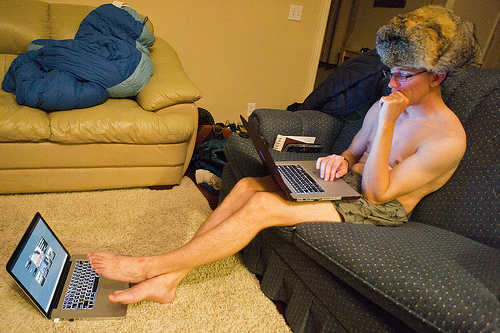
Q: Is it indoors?
A: Yes, it is indoors.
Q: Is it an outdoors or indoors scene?
A: It is indoors.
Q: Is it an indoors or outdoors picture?
A: It is indoors.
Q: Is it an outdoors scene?
A: No, it is indoors.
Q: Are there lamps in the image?
A: No, there are no lamps.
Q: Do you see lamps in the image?
A: No, there are no lamps.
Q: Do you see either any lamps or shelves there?
A: No, there are no lamps or shelves.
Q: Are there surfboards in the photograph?
A: No, there are no surfboards.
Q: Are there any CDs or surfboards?
A: No, there are no surfboards or cds.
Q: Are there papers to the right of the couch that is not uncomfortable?
A: Yes, there are papers to the right of the couch.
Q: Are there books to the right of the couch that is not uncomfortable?
A: No, there are papers to the right of the couch.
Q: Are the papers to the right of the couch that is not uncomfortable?
A: Yes, the papers are to the right of the couch.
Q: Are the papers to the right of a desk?
A: No, the papers are to the right of the couch.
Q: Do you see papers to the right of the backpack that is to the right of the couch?
A: Yes, there are papers to the right of the backpack.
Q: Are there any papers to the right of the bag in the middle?
A: Yes, there are papers to the right of the backpack.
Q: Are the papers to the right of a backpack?
A: Yes, the papers are to the right of a backpack.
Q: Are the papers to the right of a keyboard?
A: No, the papers are to the right of a backpack.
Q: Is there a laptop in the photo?
A: Yes, there is a laptop.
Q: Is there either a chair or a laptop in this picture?
A: Yes, there is a laptop.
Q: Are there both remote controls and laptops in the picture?
A: No, there is a laptop but no remote controls.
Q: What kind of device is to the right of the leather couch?
A: The device is a laptop.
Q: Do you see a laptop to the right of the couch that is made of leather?
A: Yes, there is a laptop to the right of the couch.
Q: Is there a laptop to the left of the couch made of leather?
A: No, the laptop is to the right of the couch.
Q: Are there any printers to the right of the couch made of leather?
A: No, there is a laptop to the right of the couch.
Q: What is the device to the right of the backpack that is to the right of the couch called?
A: The device is a laptop.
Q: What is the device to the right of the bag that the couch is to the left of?
A: The device is a laptop.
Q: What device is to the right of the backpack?
A: The device is a laptop.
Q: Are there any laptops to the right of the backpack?
A: Yes, there is a laptop to the right of the backpack.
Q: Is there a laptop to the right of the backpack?
A: Yes, there is a laptop to the right of the backpack.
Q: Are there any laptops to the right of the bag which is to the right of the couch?
A: Yes, there is a laptop to the right of the backpack.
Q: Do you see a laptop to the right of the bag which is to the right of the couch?
A: Yes, there is a laptop to the right of the backpack.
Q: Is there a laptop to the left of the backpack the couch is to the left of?
A: No, the laptop is to the right of the backpack.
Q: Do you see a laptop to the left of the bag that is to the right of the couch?
A: No, the laptop is to the right of the backpack.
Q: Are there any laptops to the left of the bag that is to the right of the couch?
A: No, the laptop is to the right of the backpack.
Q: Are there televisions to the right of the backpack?
A: No, there is a laptop to the right of the backpack.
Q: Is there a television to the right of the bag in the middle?
A: No, there is a laptop to the right of the backpack.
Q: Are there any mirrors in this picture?
A: No, there are no mirrors.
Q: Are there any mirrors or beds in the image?
A: No, there are no mirrors or beds.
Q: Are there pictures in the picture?
A: No, there are no pictures.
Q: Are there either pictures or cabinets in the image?
A: No, there are no pictures or cabinets.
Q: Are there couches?
A: Yes, there is a couch.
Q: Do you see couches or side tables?
A: Yes, there is a couch.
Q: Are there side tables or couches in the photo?
A: Yes, there is a couch.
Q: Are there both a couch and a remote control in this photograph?
A: No, there is a couch but no remote controls.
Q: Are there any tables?
A: No, there are no tables.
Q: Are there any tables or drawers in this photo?
A: No, there are no tables or drawers.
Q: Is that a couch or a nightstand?
A: That is a couch.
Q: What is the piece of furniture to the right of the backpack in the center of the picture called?
A: The piece of furniture is a couch.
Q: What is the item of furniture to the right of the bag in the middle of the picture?
A: The piece of furniture is a couch.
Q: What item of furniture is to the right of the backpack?
A: The piece of furniture is a couch.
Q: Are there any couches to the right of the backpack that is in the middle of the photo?
A: Yes, there is a couch to the right of the backpack.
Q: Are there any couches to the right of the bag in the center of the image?
A: Yes, there is a couch to the right of the backpack.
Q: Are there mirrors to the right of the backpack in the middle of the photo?
A: No, there is a couch to the right of the backpack.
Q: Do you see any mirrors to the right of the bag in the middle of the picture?
A: No, there is a couch to the right of the backpack.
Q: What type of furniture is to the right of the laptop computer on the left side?
A: The piece of furniture is a couch.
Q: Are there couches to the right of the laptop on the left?
A: Yes, there is a couch to the right of the laptop.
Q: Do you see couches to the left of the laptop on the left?
A: No, the couch is to the right of the laptop.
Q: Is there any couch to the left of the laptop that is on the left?
A: No, the couch is to the right of the laptop.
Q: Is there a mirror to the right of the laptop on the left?
A: No, there is a couch to the right of the laptop.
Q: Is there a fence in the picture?
A: No, there are no fences.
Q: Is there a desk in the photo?
A: No, there are no desks.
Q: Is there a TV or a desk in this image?
A: No, there are no desks or televisions.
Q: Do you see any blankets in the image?
A: Yes, there is a blanket.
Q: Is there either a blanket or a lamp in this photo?
A: Yes, there is a blanket.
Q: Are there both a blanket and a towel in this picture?
A: No, there is a blanket but no towels.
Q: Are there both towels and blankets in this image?
A: No, there is a blanket but no towels.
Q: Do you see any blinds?
A: No, there are no blinds.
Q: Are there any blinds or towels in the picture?
A: No, there are no blinds or towels.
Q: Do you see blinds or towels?
A: No, there are no blinds or towels.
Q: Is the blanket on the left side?
A: Yes, the blanket is on the left of the image.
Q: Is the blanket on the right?
A: No, the blanket is on the left of the image.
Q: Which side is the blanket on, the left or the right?
A: The blanket is on the left of the image.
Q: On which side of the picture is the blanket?
A: The blanket is on the left of the image.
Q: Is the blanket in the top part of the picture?
A: Yes, the blanket is in the top of the image.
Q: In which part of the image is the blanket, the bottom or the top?
A: The blanket is in the top of the image.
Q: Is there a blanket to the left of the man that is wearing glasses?
A: Yes, there is a blanket to the left of the man.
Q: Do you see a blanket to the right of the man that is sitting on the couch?
A: No, the blanket is to the left of the man.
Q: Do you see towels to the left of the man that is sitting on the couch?
A: No, there is a blanket to the left of the man.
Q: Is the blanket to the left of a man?
A: Yes, the blanket is to the left of a man.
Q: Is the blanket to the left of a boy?
A: No, the blanket is to the left of a man.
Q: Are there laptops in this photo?
A: Yes, there is a laptop.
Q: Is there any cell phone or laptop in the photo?
A: Yes, there is a laptop.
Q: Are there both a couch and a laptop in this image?
A: Yes, there are both a laptop and a couch.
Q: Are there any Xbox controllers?
A: No, there are no Xbox controllers.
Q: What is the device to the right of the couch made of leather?
A: The device is a laptop.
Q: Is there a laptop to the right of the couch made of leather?
A: Yes, there is a laptop to the right of the couch.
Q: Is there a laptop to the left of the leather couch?
A: No, the laptop is to the right of the couch.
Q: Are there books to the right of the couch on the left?
A: No, there is a laptop to the right of the couch.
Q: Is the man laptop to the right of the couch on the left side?
A: Yes, the laptop is to the right of the couch.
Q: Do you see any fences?
A: No, there are no fences.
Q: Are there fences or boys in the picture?
A: No, there are no fences or boys.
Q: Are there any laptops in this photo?
A: Yes, there is a laptop.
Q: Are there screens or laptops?
A: Yes, there is a laptop.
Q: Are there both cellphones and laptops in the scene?
A: No, there is a laptop but no cell phones.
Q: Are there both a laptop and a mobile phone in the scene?
A: No, there is a laptop but no cell phones.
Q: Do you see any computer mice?
A: No, there are no computer mice.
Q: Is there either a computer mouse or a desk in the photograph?
A: No, there are no computer mice or desks.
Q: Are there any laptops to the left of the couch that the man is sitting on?
A: Yes, there is a laptop to the left of the couch.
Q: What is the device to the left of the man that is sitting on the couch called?
A: The device is a laptop.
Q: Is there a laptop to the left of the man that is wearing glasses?
A: Yes, there is a laptop to the left of the man.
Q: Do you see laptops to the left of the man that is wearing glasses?
A: Yes, there is a laptop to the left of the man.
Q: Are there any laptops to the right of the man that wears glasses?
A: No, the laptop is to the left of the man.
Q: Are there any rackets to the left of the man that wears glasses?
A: No, there is a laptop to the left of the man.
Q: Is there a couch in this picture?
A: Yes, there is a couch.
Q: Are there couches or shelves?
A: Yes, there is a couch.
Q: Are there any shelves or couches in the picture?
A: Yes, there is a couch.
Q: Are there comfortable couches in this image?
A: Yes, there is a comfortable couch.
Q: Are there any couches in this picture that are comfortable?
A: Yes, there is a couch that is comfortable.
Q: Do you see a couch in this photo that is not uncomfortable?
A: Yes, there is an comfortable couch.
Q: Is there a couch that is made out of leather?
A: Yes, there is a couch that is made of leather.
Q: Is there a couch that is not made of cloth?
A: Yes, there is a couch that is made of leather.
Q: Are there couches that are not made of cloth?
A: Yes, there is a couch that is made of leather.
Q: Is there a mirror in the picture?
A: No, there are no mirrors.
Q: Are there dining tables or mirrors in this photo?
A: No, there are no mirrors or dining tables.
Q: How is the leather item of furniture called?
A: The piece of furniture is a couch.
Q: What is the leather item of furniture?
A: The piece of furniture is a couch.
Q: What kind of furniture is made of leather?
A: The furniture is a couch.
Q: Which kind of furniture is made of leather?
A: The furniture is a couch.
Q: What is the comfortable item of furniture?
A: The piece of furniture is a couch.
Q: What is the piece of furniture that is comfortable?
A: The piece of furniture is a couch.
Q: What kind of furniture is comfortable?
A: The furniture is a couch.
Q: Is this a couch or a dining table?
A: This is a couch.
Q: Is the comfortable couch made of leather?
A: Yes, the couch is made of leather.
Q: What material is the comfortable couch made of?
A: The couch is made of leather.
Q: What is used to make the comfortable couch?
A: The couch is made of leather.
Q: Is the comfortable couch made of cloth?
A: No, the couch is made of leather.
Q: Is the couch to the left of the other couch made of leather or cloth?
A: The couch is made of leather.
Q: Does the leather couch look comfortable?
A: Yes, the couch is comfortable.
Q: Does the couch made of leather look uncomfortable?
A: No, the couch is comfortable.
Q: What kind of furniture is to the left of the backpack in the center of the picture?
A: The piece of furniture is a couch.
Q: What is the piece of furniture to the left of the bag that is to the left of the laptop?
A: The piece of furniture is a couch.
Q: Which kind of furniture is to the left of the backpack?
A: The piece of furniture is a couch.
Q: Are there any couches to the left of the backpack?
A: Yes, there is a couch to the left of the backpack.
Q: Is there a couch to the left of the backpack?
A: Yes, there is a couch to the left of the backpack.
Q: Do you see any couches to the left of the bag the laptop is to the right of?
A: Yes, there is a couch to the left of the backpack.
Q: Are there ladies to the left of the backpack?
A: No, there is a couch to the left of the backpack.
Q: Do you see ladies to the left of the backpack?
A: No, there is a couch to the left of the backpack.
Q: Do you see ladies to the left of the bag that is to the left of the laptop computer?
A: No, there is a couch to the left of the backpack.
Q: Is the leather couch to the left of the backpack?
A: Yes, the couch is to the left of the backpack.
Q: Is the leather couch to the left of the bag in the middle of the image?
A: Yes, the couch is to the left of the backpack.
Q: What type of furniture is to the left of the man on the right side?
A: The piece of furniture is a couch.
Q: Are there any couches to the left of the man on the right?
A: Yes, there is a couch to the left of the man.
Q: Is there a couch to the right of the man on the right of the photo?
A: No, the couch is to the left of the man.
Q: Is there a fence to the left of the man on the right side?
A: No, there is a couch to the left of the man.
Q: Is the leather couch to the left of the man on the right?
A: Yes, the couch is to the left of the man.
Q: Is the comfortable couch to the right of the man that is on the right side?
A: No, the couch is to the left of the man.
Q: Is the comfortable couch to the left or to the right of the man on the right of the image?
A: The couch is to the left of the man.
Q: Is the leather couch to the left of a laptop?
A: Yes, the couch is to the left of a laptop.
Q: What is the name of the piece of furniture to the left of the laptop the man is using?
A: The piece of furniture is a couch.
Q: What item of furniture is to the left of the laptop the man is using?
A: The piece of furniture is a couch.